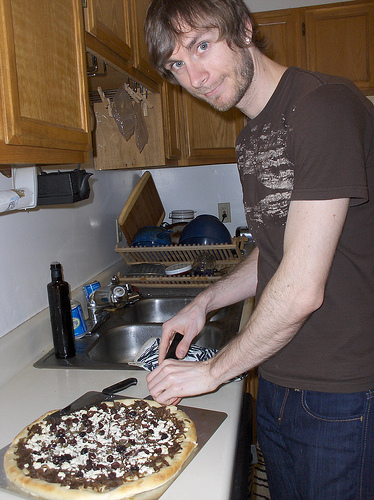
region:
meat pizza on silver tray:
[1, 389, 200, 498]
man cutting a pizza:
[124, 1, 372, 497]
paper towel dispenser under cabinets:
[0, 167, 46, 218]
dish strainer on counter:
[110, 238, 252, 288]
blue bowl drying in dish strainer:
[178, 211, 232, 252]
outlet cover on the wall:
[212, 198, 239, 228]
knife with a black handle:
[55, 371, 145, 418]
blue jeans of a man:
[253, 377, 373, 498]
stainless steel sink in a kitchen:
[92, 316, 137, 377]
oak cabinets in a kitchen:
[3, 2, 95, 162]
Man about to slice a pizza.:
[102, 241, 264, 493]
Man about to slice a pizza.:
[144, 208, 292, 432]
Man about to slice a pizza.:
[91, 181, 241, 425]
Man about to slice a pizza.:
[113, 189, 371, 381]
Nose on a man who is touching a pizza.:
[185, 59, 212, 87]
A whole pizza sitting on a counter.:
[5, 396, 193, 498]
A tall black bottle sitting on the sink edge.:
[48, 261, 76, 359]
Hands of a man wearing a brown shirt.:
[145, 300, 208, 411]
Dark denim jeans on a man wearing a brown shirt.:
[254, 371, 373, 499]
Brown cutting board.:
[117, 170, 167, 245]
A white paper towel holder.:
[0, 165, 39, 213]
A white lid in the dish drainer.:
[162, 262, 195, 275]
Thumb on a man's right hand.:
[173, 333, 195, 359]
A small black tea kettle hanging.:
[33, 161, 93, 205]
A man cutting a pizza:
[0, 342, 243, 494]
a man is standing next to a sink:
[0, 262, 276, 390]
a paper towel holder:
[0, 145, 53, 242]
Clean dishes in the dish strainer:
[96, 178, 225, 293]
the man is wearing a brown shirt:
[199, 45, 337, 371]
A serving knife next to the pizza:
[44, 363, 132, 421]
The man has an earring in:
[219, 4, 254, 59]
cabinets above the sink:
[0, 10, 105, 132]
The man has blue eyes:
[160, 30, 213, 78]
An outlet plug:
[217, 196, 230, 233]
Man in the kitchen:
[146, 0, 373, 499]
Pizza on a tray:
[3, 398, 197, 498]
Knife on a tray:
[42, 376, 137, 420]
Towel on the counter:
[127, 334, 248, 385]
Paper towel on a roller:
[0, 187, 34, 209]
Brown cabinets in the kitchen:
[2, 1, 371, 171]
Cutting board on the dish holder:
[117, 169, 166, 245]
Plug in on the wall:
[216, 201, 230, 223]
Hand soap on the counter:
[69, 295, 87, 338]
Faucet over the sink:
[86, 285, 128, 331]